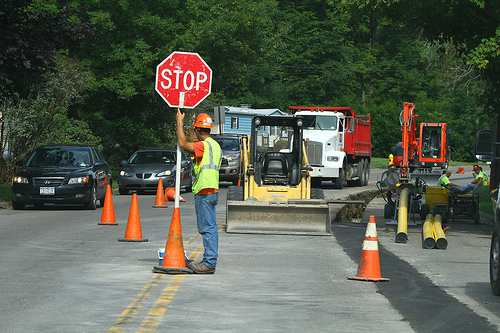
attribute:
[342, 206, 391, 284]
cone — orange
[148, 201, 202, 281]
cone — orange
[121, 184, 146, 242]
cone — orange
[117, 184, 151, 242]
cone — orange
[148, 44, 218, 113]
sign — octogon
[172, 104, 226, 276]
man — directing traffic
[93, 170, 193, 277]
cones — orange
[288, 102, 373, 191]
dump truck — red, white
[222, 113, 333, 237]
bulldozer — small, yellow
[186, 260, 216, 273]
boot — brown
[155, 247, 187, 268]
water cooler — blue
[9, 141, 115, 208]
car — black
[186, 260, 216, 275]
shoe — brown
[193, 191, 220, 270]
pants — blue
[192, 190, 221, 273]
jeans — blue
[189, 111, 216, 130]
helmet — orange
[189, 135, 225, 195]
safety vest — green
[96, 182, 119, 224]
traffic cone — orange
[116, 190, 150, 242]
traffic cone — orange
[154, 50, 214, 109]
stop sign — red, white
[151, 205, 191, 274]
safety cone — orange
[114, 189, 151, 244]
safety cone — orange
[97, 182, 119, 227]
safety cone — orange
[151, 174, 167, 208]
safety cone — orange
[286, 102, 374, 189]
truck — red, white, black, heavy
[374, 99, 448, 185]
tractor — red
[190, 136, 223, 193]
vest — green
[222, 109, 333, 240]
tractor — yellow, black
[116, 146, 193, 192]
car — silver